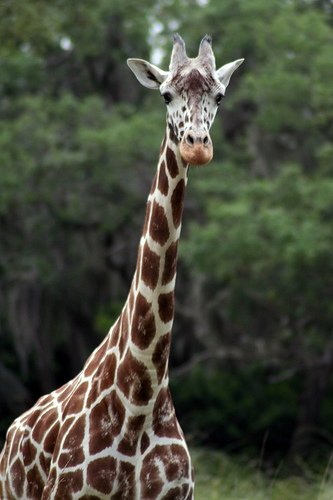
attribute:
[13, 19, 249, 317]
trees — blurry, green, tall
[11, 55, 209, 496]
giraffe — brown, white, visable, tall, staring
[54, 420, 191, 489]
spots — large, brown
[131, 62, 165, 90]
ear — white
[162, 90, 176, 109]
eye — black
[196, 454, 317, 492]
grass — green, tall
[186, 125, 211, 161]
nose — black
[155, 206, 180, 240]
fur — white, brown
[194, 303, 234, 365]
bark — brown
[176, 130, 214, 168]
snout — tan, long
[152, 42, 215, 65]
horns — knobby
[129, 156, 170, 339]
neck — long, thin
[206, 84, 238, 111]
eye — black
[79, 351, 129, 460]
print — brown, white